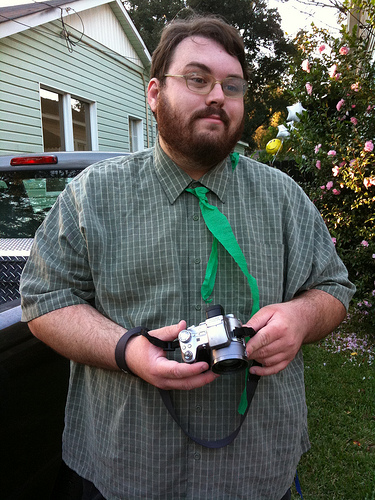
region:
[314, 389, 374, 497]
a dark green bush.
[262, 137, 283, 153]
a small yellow smiley face.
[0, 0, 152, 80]
a white black and green roof top.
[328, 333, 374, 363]
a bunch of flowers on the grass.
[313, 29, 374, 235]
a bunch of pink roses on the tree.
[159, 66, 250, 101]
a man is wearing clear glasses.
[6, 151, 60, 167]
a red light is on top of the vehicle.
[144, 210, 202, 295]
a man is wearing a grey stripped shirt with buttons.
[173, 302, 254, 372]
a man is holding a grey camera.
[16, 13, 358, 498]
a man is smiling holding a camera in his hands.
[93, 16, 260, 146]
a man wearing glasses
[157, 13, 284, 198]
a man with brown hair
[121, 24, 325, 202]
a man with a beard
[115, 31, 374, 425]
a man weraing a shirt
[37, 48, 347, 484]
a man wearing a button shirt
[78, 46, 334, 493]
a man standing outside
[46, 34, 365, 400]
a man that is outside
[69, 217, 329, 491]
a man holding a camera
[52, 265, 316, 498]
a camera with a strap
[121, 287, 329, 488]
a strap on a camera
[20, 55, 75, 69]
Part of the building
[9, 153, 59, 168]
A red light on the truck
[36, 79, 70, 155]
A window on the building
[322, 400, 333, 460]
Part of the green grass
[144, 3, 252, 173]
The head of the person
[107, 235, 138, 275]
Part of the shirt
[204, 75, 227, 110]
The nose of the person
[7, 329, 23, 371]
Part of the truck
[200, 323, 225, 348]
Part of the camera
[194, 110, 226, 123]
The mouth of the person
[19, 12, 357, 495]
man holding a camera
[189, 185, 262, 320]
green tie man is wearing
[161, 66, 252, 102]
eyeglasses man is wearing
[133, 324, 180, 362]
black strap of the camera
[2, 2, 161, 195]
green and white house in back of the man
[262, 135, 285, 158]
yellow flower on the bushes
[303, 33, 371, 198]
pink flowers on bush in back of the man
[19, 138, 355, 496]
green shirt man is wearing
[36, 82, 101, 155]
windows of the green and white house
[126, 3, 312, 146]
tall tree in back of the house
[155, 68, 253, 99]
a man's eyeglasses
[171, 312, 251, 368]
a gray digital camera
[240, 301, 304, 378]
the hand of a man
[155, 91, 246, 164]
a man's brown beard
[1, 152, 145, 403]
part of a gray truck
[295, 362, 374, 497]
a section of green grass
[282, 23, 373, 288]
a pink rose tree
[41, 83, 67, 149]
a window of a home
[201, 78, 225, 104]
the nose of a man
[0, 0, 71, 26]
part of a roof top